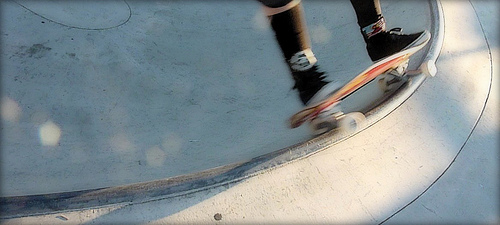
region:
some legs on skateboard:
[259, 2, 461, 119]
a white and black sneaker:
[286, 53, 330, 100]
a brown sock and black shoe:
[269, 2, 340, 89]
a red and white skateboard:
[296, 64, 429, 115]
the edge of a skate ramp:
[263, 142, 443, 197]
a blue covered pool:
[15, 18, 242, 148]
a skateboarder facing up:
[273, 5, 448, 119]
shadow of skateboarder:
[47, 166, 267, 223]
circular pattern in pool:
[11, 1, 155, 35]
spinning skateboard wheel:
[305, 113, 377, 140]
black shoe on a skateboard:
[363, 20, 428, 62]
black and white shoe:
[283, 48, 342, 108]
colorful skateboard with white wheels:
[283, 36, 443, 128]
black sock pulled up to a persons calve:
[263, 6, 318, 53]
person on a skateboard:
[265, 2, 436, 139]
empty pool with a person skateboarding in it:
[0, 1, 447, 215]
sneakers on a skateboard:
[286, 18, 438, 133]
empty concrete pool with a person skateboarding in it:
[1, 0, 448, 220]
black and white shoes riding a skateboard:
[287, 22, 437, 137]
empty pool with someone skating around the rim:
[1, 2, 446, 220]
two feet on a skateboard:
[261, 8, 436, 150]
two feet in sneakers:
[249, 9, 439, 126]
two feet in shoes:
[280, 5, 440, 110]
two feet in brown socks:
[262, 0, 442, 140]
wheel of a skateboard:
[415, 48, 438, 84]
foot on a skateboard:
[252, 50, 349, 160]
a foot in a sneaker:
[283, 43, 343, 118]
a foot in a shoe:
[279, 31, 340, 143]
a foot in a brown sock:
[260, 5, 336, 110]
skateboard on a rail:
[285, 20, 446, 165]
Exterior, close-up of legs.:
[5, 5, 498, 222]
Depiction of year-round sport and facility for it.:
[0, 5, 490, 215]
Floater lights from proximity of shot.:
[0, 95, 215, 168]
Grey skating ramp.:
[23, 5, 489, 218]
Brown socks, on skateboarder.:
[267, 5, 363, 63]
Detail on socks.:
[292, 18, 387, 74]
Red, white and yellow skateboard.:
[290, 21, 425, 118]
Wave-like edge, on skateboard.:
[346, 53, 408, 86]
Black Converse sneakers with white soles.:
[295, 30, 430, 95]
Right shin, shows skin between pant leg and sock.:
[264, 4, 309, 19]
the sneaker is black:
[263, 20, 482, 117]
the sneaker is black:
[274, 48, 419, 117]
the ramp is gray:
[119, 83, 197, 171]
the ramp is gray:
[213, 81, 318, 195]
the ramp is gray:
[142, 110, 237, 197]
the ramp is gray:
[136, 163, 203, 220]